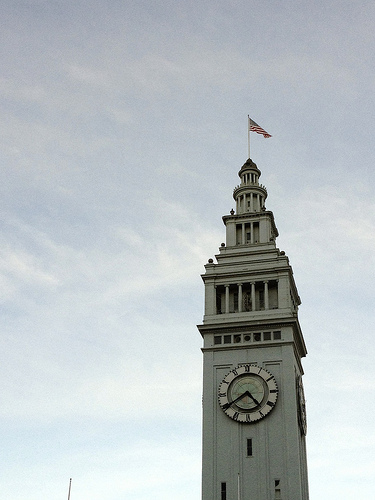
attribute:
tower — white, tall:
[194, 113, 310, 499]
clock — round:
[217, 364, 279, 426]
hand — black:
[245, 390, 261, 406]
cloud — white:
[4, 243, 67, 294]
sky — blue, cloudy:
[0, 0, 374, 499]